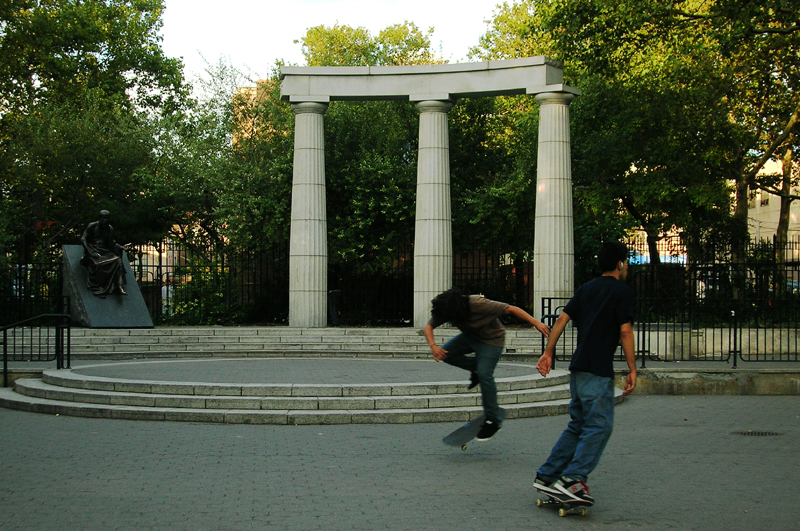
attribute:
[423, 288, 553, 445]
skater — brown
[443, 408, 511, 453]
skateboard — silver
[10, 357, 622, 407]
steps — circular